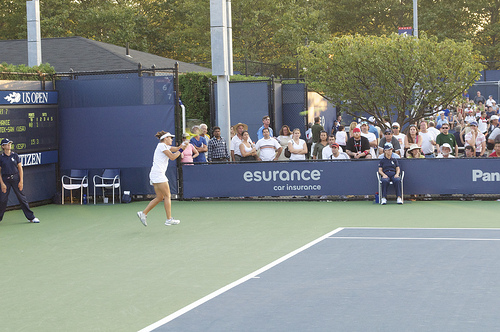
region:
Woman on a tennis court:
[131, 120, 186, 227]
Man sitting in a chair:
[361, 149, 416, 200]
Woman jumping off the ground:
[120, 200, 225, 240]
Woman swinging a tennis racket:
[157, 113, 208, 171]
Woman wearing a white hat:
[156, 130, 179, 145]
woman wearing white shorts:
[136, 165, 188, 192]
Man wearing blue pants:
[5, 175, 35, 217]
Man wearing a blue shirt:
[6, 152, 38, 197]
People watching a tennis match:
[226, 110, 463, 164]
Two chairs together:
[52, 158, 129, 216]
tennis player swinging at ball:
[132, 123, 209, 221]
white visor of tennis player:
[155, 127, 175, 139]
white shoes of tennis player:
[132, 202, 185, 227]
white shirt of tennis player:
[151, 144, 170, 168]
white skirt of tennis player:
[145, 172, 170, 184]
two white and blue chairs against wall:
[58, 164, 122, 202]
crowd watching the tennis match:
[190, 98, 498, 158]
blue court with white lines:
[133, 207, 499, 320]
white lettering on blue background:
[240, 167, 322, 194]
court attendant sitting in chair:
[366, 145, 408, 205]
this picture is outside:
[26, 30, 451, 319]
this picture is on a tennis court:
[105, 93, 450, 330]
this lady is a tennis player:
[136, 121, 201, 206]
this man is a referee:
[363, 132, 431, 214]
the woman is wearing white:
[158, 127, 185, 177]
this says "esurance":
[238, 164, 375, 197]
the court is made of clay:
[48, 232, 259, 280]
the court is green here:
[44, 248, 156, 327]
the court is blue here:
[312, 273, 426, 326]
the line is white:
[217, 271, 274, 288]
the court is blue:
[328, 250, 421, 306]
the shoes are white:
[125, 204, 189, 233]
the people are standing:
[210, 106, 327, 157]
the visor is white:
[156, 127, 174, 140]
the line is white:
[185, 265, 262, 300]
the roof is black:
[63, 44, 105, 66]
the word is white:
[234, 163, 324, 185]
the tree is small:
[300, 17, 488, 118]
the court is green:
[64, 230, 147, 287]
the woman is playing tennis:
[125, 108, 205, 234]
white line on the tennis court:
[131, 221, 346, 330]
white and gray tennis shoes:
[134, 209, 183, 229]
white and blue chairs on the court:
[58, 162, 124, 207]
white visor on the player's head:
[158, 130, 176, 142]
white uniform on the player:
[146, 141, 173, 183]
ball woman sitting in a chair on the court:
[373, 139, 405, 205]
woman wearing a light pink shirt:
[181, 141, 195, 165]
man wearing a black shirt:
[344, 134, 370, 154]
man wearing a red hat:
[349, 123, 363, 134]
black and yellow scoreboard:
[0, 103, 63, 155]